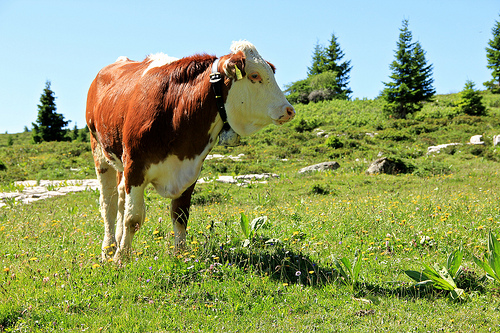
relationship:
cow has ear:
[71, 38, 296, 264] [217, 53, 247, 85]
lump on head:
[234, 25, 276, 57] [211, 34, 299, 151]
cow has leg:
[71, 38, 296, 264] [165, 187, 196, 264]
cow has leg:
[71, 38, 296, 264] [114, 171, 151, 264]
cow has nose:
[71, 38, 296, 264] [284, 105, 296, 122]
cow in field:
[71, 38, 296, 264] [0, 89, 499, 331]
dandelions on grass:
[378, 222, 410, 257] [5, 128, 495, 325]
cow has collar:
[71, 38, 296, 264] [207, 52, 232, 135]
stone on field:
[366, 155, 414, 174] [0, 89, 499, 331]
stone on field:
[468, 133, 484, 145] [0, 89, 499, 331]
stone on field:
[318, 130, 328, 139] [0, 89, 499, 331]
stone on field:
[298, 160, 342, 170] [0, 89, 499, 331]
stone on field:
[424, 141, 464, 152] [0, 89, 499, 331]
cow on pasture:
[71, 38, 296, 264] [332, 93, 485, 288]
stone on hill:
[366, 155, 414, 174] [0, 89, 499, 331]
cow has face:
[71, 35, 323, 260] [212, 25, 313, 170]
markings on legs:
[122, 193, 146, 266] [18, 97, 235, 291]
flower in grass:
[39, 272, 51, 284] [100, 189, 465, 325]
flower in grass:
[307, 267, 313, 274] [100, 189, 465, 325]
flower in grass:
[441, 210, 452, 218] [100, 189, 465, 325]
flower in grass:
[88, 260, 101, 268] [100, 189, 465, 325]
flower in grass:
[292, 267, 302, 277] [100, 189, 465, 325]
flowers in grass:
[0, 225, 205, 275] [264, 227, 371, 330]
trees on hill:
[283, 31, 353, 101] [266, 92, 481, 162]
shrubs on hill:
[369, 89, 494, 131] [301, 98, 475, 330]